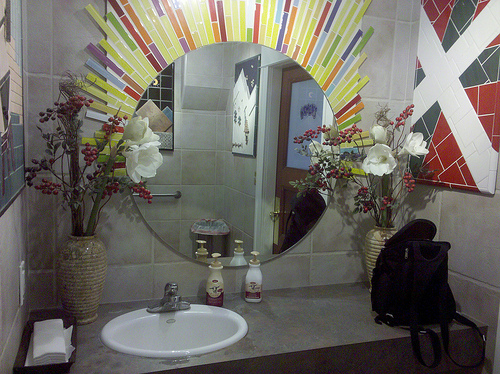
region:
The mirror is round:
[75, 25, 409, 270]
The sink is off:
[126, 268, 212, 334]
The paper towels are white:
[18, 300, 79, 367]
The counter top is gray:
[285, 304, 373, 371]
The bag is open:
[373, 215, 471, 299]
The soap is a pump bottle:
[200, 237, 241, 334]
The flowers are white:
[333, 90, 465, 210]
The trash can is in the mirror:
[180, 190, 255, 267]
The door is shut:
[254, 61, 350, 277]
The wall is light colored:
[368, 57, 407, 102]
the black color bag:
[376, 204, 472, 353]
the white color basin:
[97, 291, 252, 359]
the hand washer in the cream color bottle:
[202, 249, 231, 308]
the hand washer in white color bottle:
[240, 246, 268, 305]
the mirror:
[117, 30, 354, 276]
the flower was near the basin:
[36, 60, 164, 318]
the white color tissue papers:
[24, 318, 74, 369]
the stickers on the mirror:
[104, 11, 163, 69]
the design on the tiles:
[416, 15, 491, 201]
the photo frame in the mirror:
[222, 48, 271, 161]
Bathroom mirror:
[124, 41, 347, 266]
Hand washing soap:
[201, 253, 274, 310]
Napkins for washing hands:
[22, 308, 74, 372]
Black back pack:
[372, 213, 493, 363]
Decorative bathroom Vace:
[54, 233, 109, 330]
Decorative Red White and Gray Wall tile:
[408, 3, 497, 218]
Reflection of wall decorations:
[229, 56, 259, 166]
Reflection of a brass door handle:
[269, 196, 286, 252]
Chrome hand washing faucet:
[145, 276, 193, 321]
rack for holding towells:
[127, 186, 188, 203]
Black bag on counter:
[381, 225, 463, 352]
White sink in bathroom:
[113, 313, 239, 348]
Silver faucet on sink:
[147, 279, 193, 315]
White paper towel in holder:
[36, 318, 67, 362]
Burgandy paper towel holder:
[13, 312, 33, 372]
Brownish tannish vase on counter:
[56, 238, 110, 299]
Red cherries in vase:
[78, 136, 103, 167]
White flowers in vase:
[126, 142, 161, 182]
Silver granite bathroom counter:
[273, 300, 353, 341]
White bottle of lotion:
[243, 249, 265, 306]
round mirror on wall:
[110, 31, 350, 285]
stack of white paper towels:
[36, 309, 78, 372]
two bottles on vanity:
[199, 242, 280, 319]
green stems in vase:
[58, 210, 110, 326]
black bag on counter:
[361, 215, 486, 350]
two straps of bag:
[394, 318, 490, 372]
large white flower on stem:
[104, 140, 166, 186]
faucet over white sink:
[141, 278, 191, 323]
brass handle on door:
[263, 196, 286, 236]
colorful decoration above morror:
[133, 10, 354, 84]